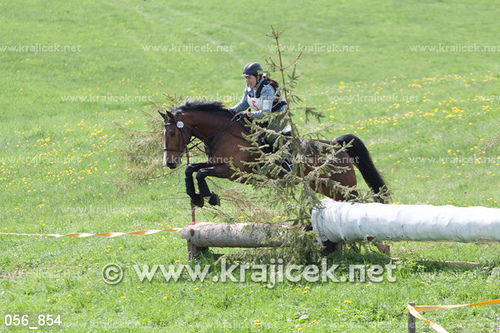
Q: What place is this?
A: It is a field.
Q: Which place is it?
A: It is a field.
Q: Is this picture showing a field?
A: Yes, it is showing a field.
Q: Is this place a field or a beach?
A: It is a field.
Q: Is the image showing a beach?
A: No, the picture is showing a field.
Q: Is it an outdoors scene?
A: Yes, it is outdoors.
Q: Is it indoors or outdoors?
A: It is outdoors.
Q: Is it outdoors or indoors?
A: It is outdoors.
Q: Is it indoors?
A: No, it is outdoors.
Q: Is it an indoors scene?
A: No, it is outdoors.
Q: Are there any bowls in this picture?
A: No, there are no bowls.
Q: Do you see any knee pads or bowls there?
A: No, there are no bowls or knee pads.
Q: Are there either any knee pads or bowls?
A: No, there are no bowls or knee pads.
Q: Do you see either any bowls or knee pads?
A: No, there are no bowls or knee pads.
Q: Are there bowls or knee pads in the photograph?
A: No, there are no bowls or knee pads.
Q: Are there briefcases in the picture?
A: No, there are no briefcases.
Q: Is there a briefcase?
A: No, there are no briefcases.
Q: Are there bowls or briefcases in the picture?
A: No, there are no briefcases or bowls.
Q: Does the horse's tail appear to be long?
A: Yes, the tail is long.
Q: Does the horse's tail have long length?
A: Yes, the tail is long.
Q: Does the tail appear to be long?
A: Yes, the tail is long.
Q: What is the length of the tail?
A: The tail is long.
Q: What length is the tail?
A: The tail is long.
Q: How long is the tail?
A: The tail is long.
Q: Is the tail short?
A: No, the tail is long.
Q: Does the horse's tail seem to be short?
A: No, the tail is long.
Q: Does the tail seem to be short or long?
A: The tail is long.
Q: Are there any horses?
A: Yes, there is a horse.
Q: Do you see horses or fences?
A: Yes, there is a horse.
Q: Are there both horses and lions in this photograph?
A: No, there is a horse but no lions.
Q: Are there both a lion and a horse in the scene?
A: No, there is a horse but no lions.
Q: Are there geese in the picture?
A: No, there are no geese.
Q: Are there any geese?
A: No, there are no geese.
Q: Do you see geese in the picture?
A: No, there are no geese.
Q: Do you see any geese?
A: No, there are no geese.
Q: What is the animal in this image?
A: The animal is a horse.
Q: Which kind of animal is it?
A: The animal is a horse.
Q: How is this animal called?
A: This is a horse.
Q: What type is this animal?
A: This is a horse.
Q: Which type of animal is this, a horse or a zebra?
A: This is a horse.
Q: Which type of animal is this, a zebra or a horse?
A: This is a horse.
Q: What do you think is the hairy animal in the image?
A: The animal is a horse.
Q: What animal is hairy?
A: The animal is a horse.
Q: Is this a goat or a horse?
A: This is a horse.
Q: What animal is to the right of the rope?
A: The animal is a horse.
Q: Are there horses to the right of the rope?
A: Yes, there is a horse to the right of the rope.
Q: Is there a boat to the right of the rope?
A: No, there is a horse to the right of the rope.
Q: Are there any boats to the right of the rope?
A: No, there is a horse to the right of the rope.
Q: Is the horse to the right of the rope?
A: Yes, the horse is to the right of the rope.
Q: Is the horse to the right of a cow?
A: No, the horse is to the right of the rope.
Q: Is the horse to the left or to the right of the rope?
A: The horse is to the right of the rope.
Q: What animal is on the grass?
A: The animal is a horse.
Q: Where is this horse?
A: The horse is on the grass.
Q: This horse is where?
A: The horse is on the grass.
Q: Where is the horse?
A: The horse is on the grass.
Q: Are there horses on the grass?
A: Yes, there is a horse on the grass.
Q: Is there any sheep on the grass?
A: No, there is a horse on the grass.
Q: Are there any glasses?
A: No, there are no glasses.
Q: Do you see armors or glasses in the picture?
A: No, there are no glasses or armors.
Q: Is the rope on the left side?
A: Yes, the rope is on the left of the image.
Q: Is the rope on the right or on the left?
A: The rope is on the left of the image.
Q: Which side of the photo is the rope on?
A: The rope is on the left of the image.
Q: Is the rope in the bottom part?
A: Yes, the rope is in the bottom of the image.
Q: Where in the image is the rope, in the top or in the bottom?
A: The rope is in the bottom of the image.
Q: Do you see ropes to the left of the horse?
A: Yes, there is a rope to the left of the horse.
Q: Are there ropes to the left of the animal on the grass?
A: Yes, there is a rope to the left of the horse.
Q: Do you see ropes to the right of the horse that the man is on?
A: No, the rope is to the left of the horse.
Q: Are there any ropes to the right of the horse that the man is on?
A: No, the rope is to the left of the horse.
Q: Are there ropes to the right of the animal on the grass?
A: No, the rope is to the left of the horse.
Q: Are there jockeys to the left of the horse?
A: No, there is a rope to the left of the horse.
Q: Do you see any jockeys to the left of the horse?
A: No, there is a rope to the left of the horse.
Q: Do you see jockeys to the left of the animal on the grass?
A: No, there is a rope to the left of the horse.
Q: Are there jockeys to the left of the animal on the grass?
A: No, there is a rope to the left of the horse.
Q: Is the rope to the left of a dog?
A: No, the rope is to the left of a horse.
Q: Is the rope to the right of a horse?
A: No, the rope is to the left of a horse.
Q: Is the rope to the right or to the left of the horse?
A: The rope is to the left of the horse.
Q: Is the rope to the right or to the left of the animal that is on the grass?
A: The rope is to the left of the horse.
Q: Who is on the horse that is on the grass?
A: The man is on the horse.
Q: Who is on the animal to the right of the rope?
A: The man is on the horse.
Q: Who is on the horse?
A: The man is on the horse.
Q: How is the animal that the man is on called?
A: The animal is a horse.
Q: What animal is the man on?
A: The man is on the horse.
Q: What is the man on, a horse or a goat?
A: The man is on a horse.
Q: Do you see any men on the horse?
A: Yes, there is a man on the horse.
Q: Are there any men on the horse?
A: Yes, there is a man on the horse.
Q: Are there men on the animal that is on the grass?
A: Yes, there is a man on the horse.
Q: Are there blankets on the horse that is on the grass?
A: No, there is a man on the horse.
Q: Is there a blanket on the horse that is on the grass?
A: No, there is a man on the horse.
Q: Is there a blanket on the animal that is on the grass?
A: No, there is a man on the horse.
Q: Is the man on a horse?
A: Yes, the man is on a horse.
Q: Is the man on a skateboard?
A: No, the man is on a horse.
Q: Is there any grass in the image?
A: Yes, there is grass.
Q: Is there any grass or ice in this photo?
A: Yes, there is grass.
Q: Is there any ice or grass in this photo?
A: Yes, there is grass.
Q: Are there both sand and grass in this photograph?
A: No, there is grass but no sand.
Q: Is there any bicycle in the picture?
A: No, there are no bicycles.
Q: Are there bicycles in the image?
A: No, there are no bicycles.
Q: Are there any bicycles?
A: No, there are no bicycles.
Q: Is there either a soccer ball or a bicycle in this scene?
A: No, there are no bicycles or soccer balls.